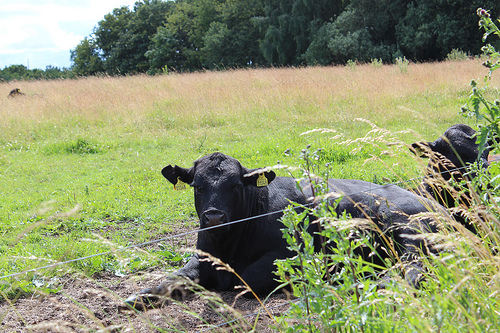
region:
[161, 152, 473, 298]
the cow is laying in the field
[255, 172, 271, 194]
the cow has a tag in its ear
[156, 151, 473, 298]
the cow is black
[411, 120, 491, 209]
this cow is hidden behind the bushes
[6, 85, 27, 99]
a cow is laying in the pasture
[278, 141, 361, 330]
flowers randomly growing in the pasture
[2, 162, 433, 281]
a wire fence keeps the cows in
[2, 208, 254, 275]
the wire is silver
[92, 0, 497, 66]
the trees are in the background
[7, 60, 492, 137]
the grass is brown and green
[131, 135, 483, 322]
A large black cow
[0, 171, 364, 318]
A small silver wire along the pasture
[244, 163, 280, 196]
A yellow tag in the cows ear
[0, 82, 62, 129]
Another black cow in the pasture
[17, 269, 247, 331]
A dirt patch in the pasture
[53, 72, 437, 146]
Extremely tall grass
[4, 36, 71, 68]
Blue sky with some white clouds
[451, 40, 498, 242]
Plants with fuzzy parts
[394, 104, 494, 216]
A cow trying to stay cool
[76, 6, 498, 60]
A line of trees in the pasture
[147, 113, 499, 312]
two black cows lying on a prairie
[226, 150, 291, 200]
a tag on right ear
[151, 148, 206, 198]
a tag on left ear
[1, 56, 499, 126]
brown grass on a field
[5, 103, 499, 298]
green grass on a field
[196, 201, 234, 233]
nostrils of a cow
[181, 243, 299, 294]
front legs of cow are folded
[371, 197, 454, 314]
back legs are on side of cow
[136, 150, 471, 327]
cow lies on dry grass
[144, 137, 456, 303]
head and body of cow are black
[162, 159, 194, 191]
The left ear of the left cow.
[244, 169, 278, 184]
The right ear of the cow on the left.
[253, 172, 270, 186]
The yellow tag on the cow's right ear on the left.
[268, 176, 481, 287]
The body of the cow on the left.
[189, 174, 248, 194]
The eyes of the cow on the left.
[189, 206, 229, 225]
The nose of the cow on the left.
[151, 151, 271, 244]
The head of the cow on the left.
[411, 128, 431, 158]
The left ear of the cow on the right.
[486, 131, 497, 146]
The right ear of the cow on the right.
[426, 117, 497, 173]
The head of the cow on the right.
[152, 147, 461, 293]
a black cow laying down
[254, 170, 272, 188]
a yellow tag in a cow's ear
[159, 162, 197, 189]
the torn ear of a cow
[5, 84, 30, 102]
a black cow hidden in the grass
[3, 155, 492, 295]
the wire of an electric fence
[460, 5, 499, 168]
a thistle plant growing next to a fence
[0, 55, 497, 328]
a grassy field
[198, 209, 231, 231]
the black nose of a cow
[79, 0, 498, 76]
trees beyond the field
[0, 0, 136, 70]
a pale blue sky